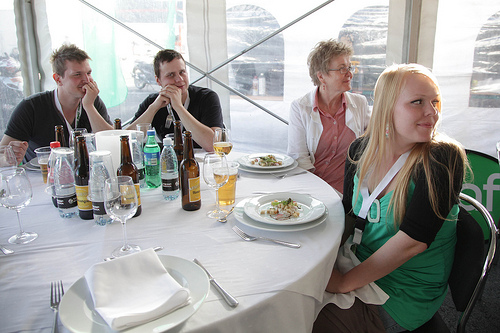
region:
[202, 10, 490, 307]
people looking on the right side in the front dinning table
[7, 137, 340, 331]
a round dinning table with white cloth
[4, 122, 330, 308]
round table with plates of food and drinks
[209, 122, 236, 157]
a glass of drink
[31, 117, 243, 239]
bottles of drinks and wine glasses on the table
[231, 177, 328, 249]
a white plate of salad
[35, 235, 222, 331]
a table napkin on top of the plate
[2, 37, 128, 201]
a guy wearing black with his left hand partially covering his mouth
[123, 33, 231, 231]
a guy wearing black on the dinning table with bottles of drinks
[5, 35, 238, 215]
two guys both wearing black shirt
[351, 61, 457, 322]
a woman sitting in a chair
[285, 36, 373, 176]
a woman sitting in a chair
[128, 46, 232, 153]
a man sitting in a chair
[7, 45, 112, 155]
a man sitting in a chair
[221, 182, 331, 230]
a white plate of food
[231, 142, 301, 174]
a white plate of food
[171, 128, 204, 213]
an empty bottle of alcohol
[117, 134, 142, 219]
an empty bottle of alcohol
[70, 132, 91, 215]
an empty bottle of alcohol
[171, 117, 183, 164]
an empty bottle of alcohol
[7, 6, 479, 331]
Four people sitting at a table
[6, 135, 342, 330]
A round table with a white table cloth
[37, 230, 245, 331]
An unused place setting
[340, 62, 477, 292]
A blonde woman in a green and black shirt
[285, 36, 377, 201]
A woman in a pink shirt with a white sweater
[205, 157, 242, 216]
A cup of beer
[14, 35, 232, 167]
Two men in black shirts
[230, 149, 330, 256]
Two plates of food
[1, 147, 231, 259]
Empty wine glasses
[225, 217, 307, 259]
A fork laying on the table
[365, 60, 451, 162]
Girl with blonde hair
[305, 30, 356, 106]
Woman with eyeglasses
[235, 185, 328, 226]
White plate with food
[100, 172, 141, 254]
Glass sitting on a table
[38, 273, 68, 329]
Fork sitting on a table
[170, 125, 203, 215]
Bottle sitting on a table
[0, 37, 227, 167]
Two men having a meal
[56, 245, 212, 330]
White plate with a napkin on top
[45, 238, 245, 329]
Table setting with silverware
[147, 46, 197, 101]
Man with brown hair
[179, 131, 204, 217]
brown long neck beer bottle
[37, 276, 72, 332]
silver fork on table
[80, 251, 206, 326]
folded white napkin on a plate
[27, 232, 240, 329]
place setting on table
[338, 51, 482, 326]
girl in green shirt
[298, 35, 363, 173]
woman in white sweater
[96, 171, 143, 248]
empty wine glass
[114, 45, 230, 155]
man in a black shirt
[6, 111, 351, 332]
round dinner table with white tablecloth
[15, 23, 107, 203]
man resting chin on hand